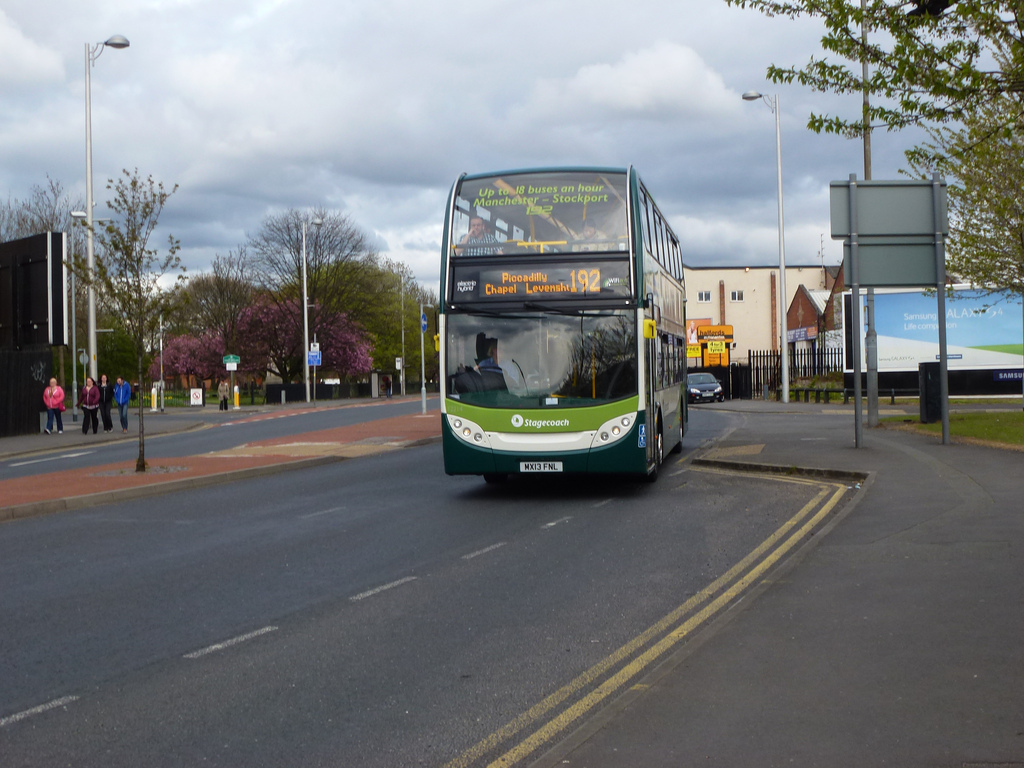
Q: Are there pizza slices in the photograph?
A: No, there are no pizza slices.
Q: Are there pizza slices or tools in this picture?
A: No, there are no pizza slices or tools.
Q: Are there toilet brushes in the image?
A: No, there are no toilet brushes.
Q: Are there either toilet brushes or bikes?
A: No, there are no toilet brushes or bikes.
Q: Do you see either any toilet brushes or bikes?
A: No, there are no toilet brushes or bikes.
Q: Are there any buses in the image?
A: Yes, there is a bus.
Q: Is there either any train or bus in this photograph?
A: Yes, there is a bus.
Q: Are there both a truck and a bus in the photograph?
A: No, there is a bus but no trucks.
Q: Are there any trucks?
A: No, there are no trucks.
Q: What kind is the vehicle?
A: The vehicle is a bus.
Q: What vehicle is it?
A: The vehicle is a bus.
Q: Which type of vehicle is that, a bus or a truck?
A: That is a bus.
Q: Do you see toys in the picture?
A: No, there are no toys.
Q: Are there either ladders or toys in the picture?
A: No, there are no toys or ladders.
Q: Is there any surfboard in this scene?
A: No, there are no surfboards.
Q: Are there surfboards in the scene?
A: No, there are no surfboards.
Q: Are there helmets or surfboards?
A: No, there are no surfboards or helmets.